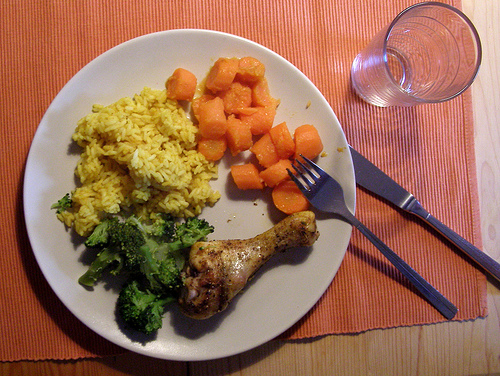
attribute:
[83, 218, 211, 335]
broccoli — green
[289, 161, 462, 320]
fork — silver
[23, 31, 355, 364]
plate — white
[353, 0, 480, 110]
glass — empty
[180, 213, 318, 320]
chicken leg — season, baked, seasoned, cooked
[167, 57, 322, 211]
carrots — tasty, steamed, cooked, cut up, diced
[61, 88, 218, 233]
rice — sticky, yellow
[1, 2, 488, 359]
placemat — pink, orange